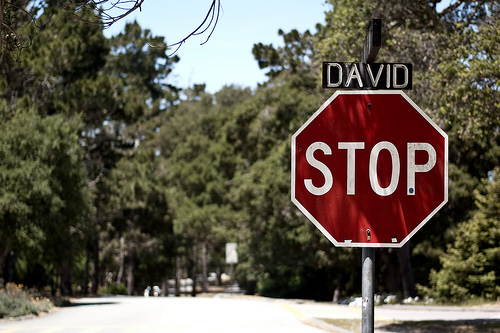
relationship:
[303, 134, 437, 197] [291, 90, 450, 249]
white letters on octagon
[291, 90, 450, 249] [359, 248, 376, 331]
octagon on pole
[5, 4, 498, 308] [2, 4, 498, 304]
grove of trees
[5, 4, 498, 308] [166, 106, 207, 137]
grove of trees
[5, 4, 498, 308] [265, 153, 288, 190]
grove of trees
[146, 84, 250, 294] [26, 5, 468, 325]
trees in background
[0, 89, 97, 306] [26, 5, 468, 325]
trees in background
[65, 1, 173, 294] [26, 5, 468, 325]
trees in background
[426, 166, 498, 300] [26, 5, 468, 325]
trees in background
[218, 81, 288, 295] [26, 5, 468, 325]
trees in background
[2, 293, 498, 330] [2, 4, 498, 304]
street lined trees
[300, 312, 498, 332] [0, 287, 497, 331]
median on road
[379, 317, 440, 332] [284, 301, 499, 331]
dirt in median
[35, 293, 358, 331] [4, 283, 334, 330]
intersection in street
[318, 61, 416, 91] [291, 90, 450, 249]
sign above octagon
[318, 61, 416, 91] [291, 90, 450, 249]
sign on octagon